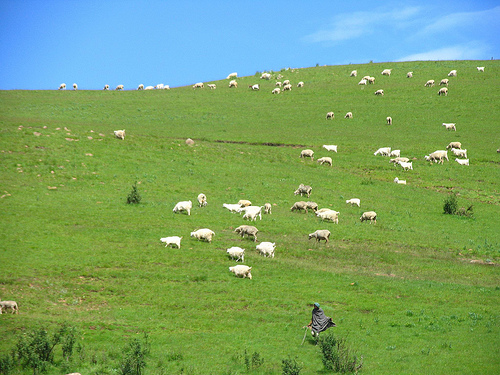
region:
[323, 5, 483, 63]
some white clouds in the sky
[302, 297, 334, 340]
a person watching the sheep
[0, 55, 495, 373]
the green grassy hill with many sheep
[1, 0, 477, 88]
the bright blue sky on a sunny day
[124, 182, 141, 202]
a little bush on the hill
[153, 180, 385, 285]
some sheep eating grass on the hill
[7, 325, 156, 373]
more green bushes on the hill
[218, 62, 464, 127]
some more sheep on the hill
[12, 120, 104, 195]
some rocks on the hill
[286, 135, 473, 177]
even more sheep on the hill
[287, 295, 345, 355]
a man on the hill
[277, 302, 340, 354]
a man walking with a cane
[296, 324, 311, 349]
the white cane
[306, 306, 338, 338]
a long coverall on the man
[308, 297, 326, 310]
a cap on his head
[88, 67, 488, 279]
a herd of sheep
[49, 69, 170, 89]
sheep ont he hill top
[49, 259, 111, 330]
patches on dirt in the grass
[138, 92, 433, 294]
sheep in a grass field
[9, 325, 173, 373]
shrubs at the bottom of the hill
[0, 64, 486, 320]
THE SHEEP ARE ON THE HILLSIDE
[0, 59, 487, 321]
THERE ARE MANY SHEEP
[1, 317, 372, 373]
THE BUSHES ARE GREEN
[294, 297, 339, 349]
THE MAN IS WEARING A GREEN HAT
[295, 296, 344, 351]
THE MAN HAS A SHEPHERDS CROOK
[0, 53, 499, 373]
THE MAN IS WITH THE SHEEP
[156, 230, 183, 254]
THIS IS A SHEEP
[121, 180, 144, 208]
THIS IS A BUSH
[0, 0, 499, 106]
THE SKY IS ALMOST CLEAR OF CLOUDS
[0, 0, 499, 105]
THE SKY IS BLUE AND BRIGHT WITH FEW CLOUDS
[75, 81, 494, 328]
group of sheep in field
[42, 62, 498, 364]
field is large and green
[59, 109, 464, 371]
field is green and grassy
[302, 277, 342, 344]
person stands in field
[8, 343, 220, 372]
trees on edge of field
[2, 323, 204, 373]
trees are green and leafy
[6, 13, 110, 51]
sky is clear and blue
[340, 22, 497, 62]
few thin clouds in sky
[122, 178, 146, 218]
small green bushes in field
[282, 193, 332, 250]
few grey sheep in herd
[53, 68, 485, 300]
flock of sheep in a field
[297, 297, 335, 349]
person walking in a field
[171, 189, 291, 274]
group of white sheep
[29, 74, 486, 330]
bright green grassy field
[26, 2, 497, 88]
brilliant blue sky with clouds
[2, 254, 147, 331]
patches of dirt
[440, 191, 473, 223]
large bush in the field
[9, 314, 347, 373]
tops of trees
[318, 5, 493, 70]
white wispy clouds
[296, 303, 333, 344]
person with a cane